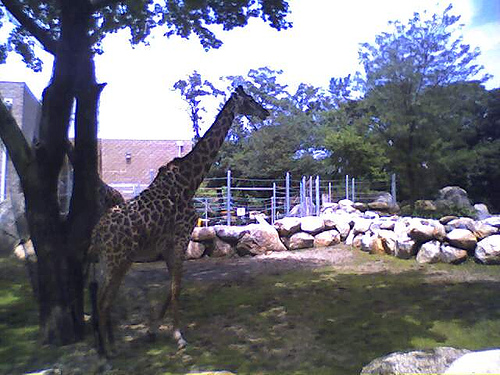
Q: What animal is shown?
A: Giraffe.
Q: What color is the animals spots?
A: Brown.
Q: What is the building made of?
A: Brick.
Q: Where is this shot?
A: Zoo.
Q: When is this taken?
A: Daytime.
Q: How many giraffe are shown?
A: 2.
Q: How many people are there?
A: 0.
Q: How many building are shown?
A: 1.